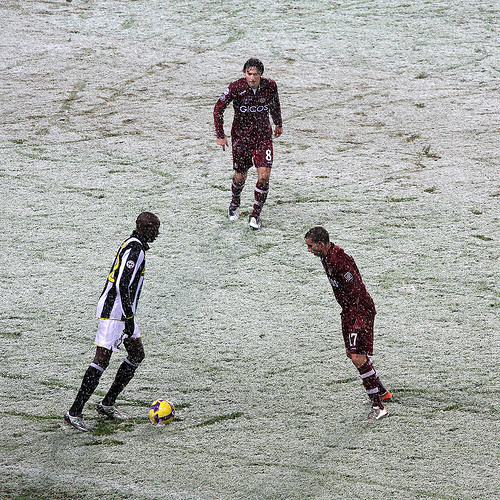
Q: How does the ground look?
A: Frosty.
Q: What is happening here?
A: A game.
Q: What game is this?
A: Soccer.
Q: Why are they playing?
A: Practice.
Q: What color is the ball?
A: Yellow and purple.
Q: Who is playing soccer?
A: Three men.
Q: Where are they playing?
A: On a field.